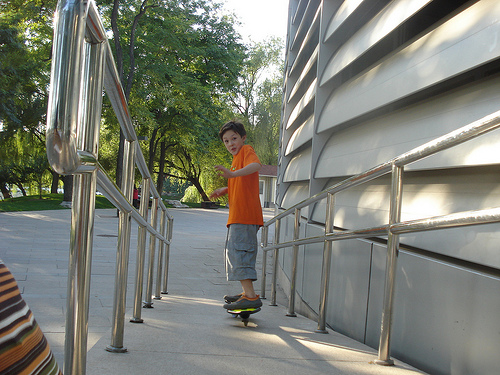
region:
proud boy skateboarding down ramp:
[90, 110, 400, 365]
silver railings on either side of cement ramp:
[25, 2, 490, 367]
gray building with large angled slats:
[275, 5, 491, 352]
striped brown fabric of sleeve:
[0, 256, 60, 367]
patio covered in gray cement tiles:
[5, 191, 280, 362]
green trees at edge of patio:
[2, 5, 227, 246]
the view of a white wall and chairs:
[206, 130, 261, 149]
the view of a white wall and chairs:
[278, 262, 294, 297]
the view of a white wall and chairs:
[281, 314, 286, 317]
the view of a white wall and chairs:
[280, 287, 295, 338]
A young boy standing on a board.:
[211, 122, 268, 326]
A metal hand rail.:
[261, 108, 497, 369]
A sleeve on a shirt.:
[0, 260, 69, 372]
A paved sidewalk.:
[75, 291, 422, 373]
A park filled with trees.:
[0, 3, 287, 206]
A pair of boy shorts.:
[223, 215, 263, 285]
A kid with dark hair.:
[214, 122, 247, 157]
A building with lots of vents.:
[274, 0, 498, 374]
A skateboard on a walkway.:
[223, 293, 263, 326]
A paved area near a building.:
[0, 208, 277, 374]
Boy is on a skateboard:
[192, 108, 279, 331]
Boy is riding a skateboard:
[203, 119, 276, 333]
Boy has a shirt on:
[212, 105, 276, 232]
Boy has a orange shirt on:
[213, 119, 270, 235]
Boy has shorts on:
[221, 219, 267, 289]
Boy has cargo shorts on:
[219, 221, 267, 289]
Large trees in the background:
[137, 5, 242, 112]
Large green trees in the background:
[138, 3, 253, 115]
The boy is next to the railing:
[205, 111, 323, 283]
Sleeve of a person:
[3, 254, 62, 373]